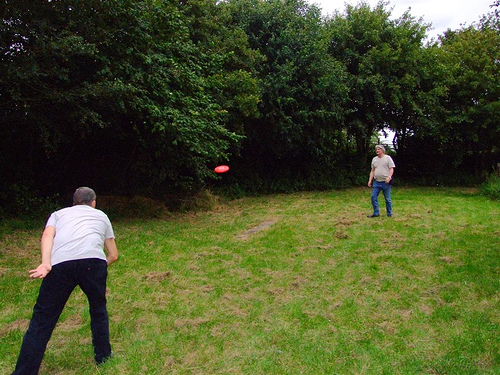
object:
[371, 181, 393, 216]
jeans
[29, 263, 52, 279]
hand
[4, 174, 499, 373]
yard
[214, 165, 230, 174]
disc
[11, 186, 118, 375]
man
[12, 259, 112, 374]
jeans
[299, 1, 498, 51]
sky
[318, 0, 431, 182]
tree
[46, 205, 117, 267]
shirt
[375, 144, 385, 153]
hair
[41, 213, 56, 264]
arm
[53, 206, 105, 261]
back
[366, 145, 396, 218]
man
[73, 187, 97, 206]
hair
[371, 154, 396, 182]
shirt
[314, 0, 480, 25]
air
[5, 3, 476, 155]
leaves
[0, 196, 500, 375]
grass